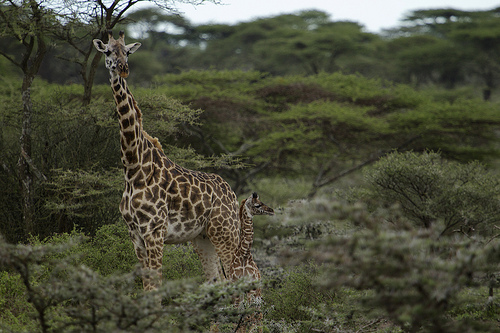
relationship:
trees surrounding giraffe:
[235, 79, 308, 143] [74, 18, 285, 331]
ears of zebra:
[62, 22, 213, 73] [90, 34, 261, 333]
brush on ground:
[81, 221, 423, 269] [35, 174, 466, 326]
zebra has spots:
[90, 48, 261, 322] [154, 179, 228, 228]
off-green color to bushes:
[347, 232, 373, 253] [273, 150, 488, 309]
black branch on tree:
[322, 169, 341, 178] [239, 52, 433, 198]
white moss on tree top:
[291, 193, 391, 242] [291, 219, 441, 276]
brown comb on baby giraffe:
[240, 188, 252, 231] [229, 180, 279, 312]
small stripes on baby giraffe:
[246, 202, 254, 226] [242, 185, 269, 283]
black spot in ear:
[91, 40, 107, 50] [88, 30, 118, 61]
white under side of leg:
[196, 232, 220, 261] [189, 223, 238, 294]